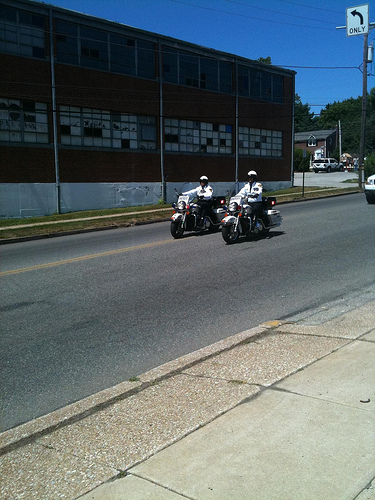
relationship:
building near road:
[0, 0, 297, 223] [2, 238, 373, 289]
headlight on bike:
[228, 201, 238, 211] [219, 198, 268, 244]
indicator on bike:
[237, 203, 243, 214] [219, 198, 268, 244]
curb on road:
[4, 178, 361, 257] [6, 205, 368, 414]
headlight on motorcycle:
[225, 199, 240, 216] [213, 192, 285, 249]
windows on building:
[59, 102, 157, 156] [0, 0, 297, 223]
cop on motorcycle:
[180, 176, 212, 227] [166, 193, 228, 237]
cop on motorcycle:
[236, 171, 263, 233] [220, 193, 284, 240]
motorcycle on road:
[166, 188, 229, 239] [0, 192, 375, 426]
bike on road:
[221, 196, 282, 244] [0, 192, 375, 426]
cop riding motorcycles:
[180, 176, 212, 227] [168, 192, 252, 240]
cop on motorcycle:
[180, 176, 212, 227] [170, 188, 226, 238]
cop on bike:
[236, 171, 263, 233] [221, 196, 282, 244]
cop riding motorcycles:
[236, 171, 263, 233] [169, 196, 286, 243]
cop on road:
[236, 171, 263, 233] [6, 205, 368, 414]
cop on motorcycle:
[238, 178, 265, 229] [223, 199, 284, 242]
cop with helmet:
[238, 178, 265, 229] [246, 169, 258, 180]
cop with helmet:
[182, 181, 215, 230] [200, 176, 209, 182]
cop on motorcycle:
[182, 181, 215, 230] [171, 198, 227, 236]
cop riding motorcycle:
[180, 176, 212, 227] [170, 188, 226, 238]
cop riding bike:
[236, 171, 263, 233] [221, 196, 282, 244]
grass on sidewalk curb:
[268, 184, 304, 191] [32, 344, 315, 403]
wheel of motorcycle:
[151, 210, 198, 234] [122, 169, 226, 246]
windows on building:
[78, 124, 107, 139] [8, 11, 291, 175]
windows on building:
[258, 135, 271, 145] [8, 11, 291, 175]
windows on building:
[164, 133, 178, 145] [8, 11, 291, 175]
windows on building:
[13, 115, 36, 128] [8, 11, 291, 175]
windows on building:
[202, 137, 213, 146] [8, 11, 291, 175]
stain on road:
[0, 297, 47, 312] [6, 205, 368, 414]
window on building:
[60, 103, 141, 149] [24, 9, 322, 262]